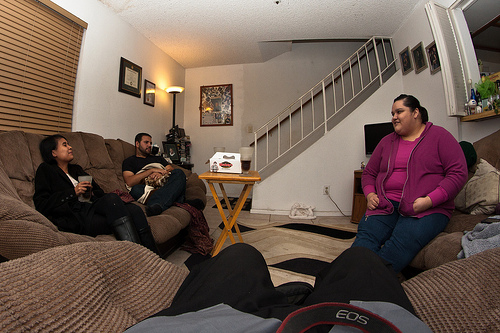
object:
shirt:
[364, 120, 462, 218]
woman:
[349, 93, 470, 277]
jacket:
[360, 120, 467, 217]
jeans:
[353, 210, 449, 277]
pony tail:
[417, 101, 429, 124]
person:
[30, 133, 162, 257]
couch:
[0, 132, 206, 244]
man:
[120, 132, 187, 213]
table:
[198, 155, 262, 261]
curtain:
[0, 0, 89, 134]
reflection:
[145, 58, 171, 93]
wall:
[48, 0, 185, 153]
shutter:
[421, 0, 472, 117]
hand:
[410, 194, 433, 213]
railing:
[246, 37, 397, 187]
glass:
[238, 144, 256, 177]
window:
[0, 2, 86, 136]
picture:
[117, 56, 147, 99]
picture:
[142, 78, 157, 108]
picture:
[197, 81, 235, 126]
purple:
[358, 123, 469, 218]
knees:
[170, 168, 186, 184]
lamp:
[166, 85, 183, 94]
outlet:
[321, 186, 334, 197]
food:
[206, 151, 239, 174]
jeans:
[133, 168, 186, 208]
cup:
[78, 175, 94, 198]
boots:
[111, 214, 140, 243]